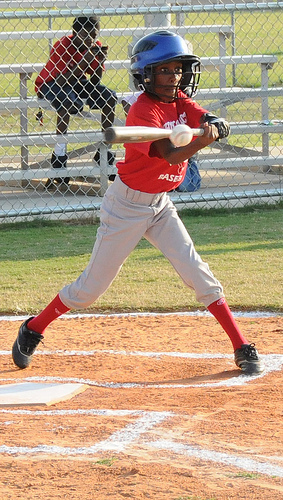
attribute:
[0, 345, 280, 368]
stripe — White 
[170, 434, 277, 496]
lines — white 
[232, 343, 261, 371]
cleat — black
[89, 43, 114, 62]
game — Small 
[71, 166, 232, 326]
pants — gary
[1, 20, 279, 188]
stands — Metal 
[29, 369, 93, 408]
plate — Home , diamond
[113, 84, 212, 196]
shirt — red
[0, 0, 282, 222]
fence — gray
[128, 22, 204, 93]
helmet — blue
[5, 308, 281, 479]
lines — white 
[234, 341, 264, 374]
shoe — black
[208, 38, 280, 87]
bleachers — metal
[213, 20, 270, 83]
chain link — Tall 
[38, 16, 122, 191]
boy — sitting